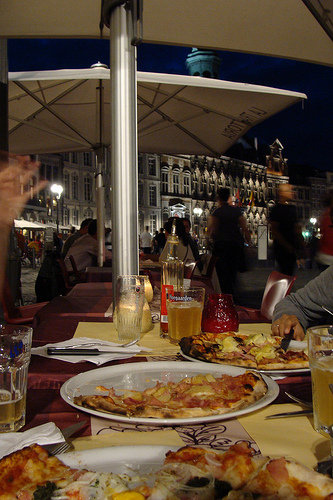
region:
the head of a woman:
[205, 172, 256, 217]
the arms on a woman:
[192, 197, 277, 251]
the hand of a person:
[263, 287, 313, 359]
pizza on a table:
[58, 304, 264, 423]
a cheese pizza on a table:
[85, 288, 295, 439]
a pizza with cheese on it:
[60, 333, 284, 456]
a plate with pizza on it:
[50, 285, 291, 441]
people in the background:
[36, 152, 290, 286]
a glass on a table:
[5, 290, 70, 438]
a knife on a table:
[62, 313, 164, 381]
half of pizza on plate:
[52, 346, 284, 449]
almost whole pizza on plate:
[182, 322, 330, 397]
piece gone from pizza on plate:
[11, 421, 269, 499]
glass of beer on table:
[153, 266, 222, 359]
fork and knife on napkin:
[40, 323, 176, 374]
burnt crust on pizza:
[174, 321, 263, 368]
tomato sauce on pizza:
[153, 431, 315, 499]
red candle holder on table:
[200, 269, 259, 349]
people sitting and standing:
[137, 147, 328, 284]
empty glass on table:
[101, 259, 151, 367]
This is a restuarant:
[104, 250, 279, 445]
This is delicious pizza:
[131, 360, 302, 426]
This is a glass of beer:
[164, 285, 209, 337]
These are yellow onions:
[147, 452, 181, 494]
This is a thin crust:
[180, 384, 242, 426]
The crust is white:
[189, 433, 301, 494]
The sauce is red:
[3, 465, 26, 484]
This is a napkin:
[30, 427, 40, 437]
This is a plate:
[79, 432, 145, 495]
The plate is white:
[115, 326, 167, 401]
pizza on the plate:
[83, 360, 264, 425]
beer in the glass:
[162, 276, 213, 328]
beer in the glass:
[153, 270, 238, 375]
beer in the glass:
[154, 280, 197, 367]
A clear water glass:
[103, 271, 146, 345]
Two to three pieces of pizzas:
[85, 385, 256, 419]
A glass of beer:
[2, 318, 24, 442]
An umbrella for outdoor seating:
[9, 124, 111, 261]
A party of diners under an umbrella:
[16, 233, 47, 266]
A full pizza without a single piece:
[183, 323, 314, 371]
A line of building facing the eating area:
[146, 154, 296, 245]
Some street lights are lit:
[300, 202, 325, 247]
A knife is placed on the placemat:
[262, 402, 320, 422]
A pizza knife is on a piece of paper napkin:
[44, 341, 167, 361]